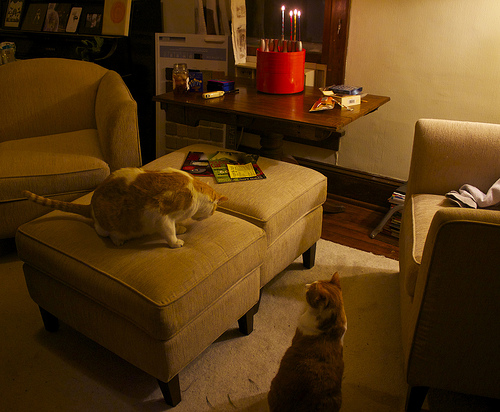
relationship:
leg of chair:
[148, 368, 203, 410] [13, 134, 374, 404]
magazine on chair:
[202, 146, 269, 187] [134, 136, 326, 293]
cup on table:
[258, 42, 304, 89] [159, 68, 386, 155]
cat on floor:
[262, 266, 344, 411] [2, 147, 410, 410]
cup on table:
[256, 39, 302, 94] [180, 70, 425, 175]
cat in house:
[262, 266, 344, 411] [4, 3, 480, 399]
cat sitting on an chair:
[37, 151, 236, 245] [13, 178, 275, 405]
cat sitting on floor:
[255, 266, 356, 409] [2, 147, 410, 410]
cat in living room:
[20, 162, 219, 249] [0, 0, 499, 410]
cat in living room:
[262, 266, 344, 411] [0, 0, 499, 410]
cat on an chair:
[20, 162, 219, 249] [13, 178, 275, 405]